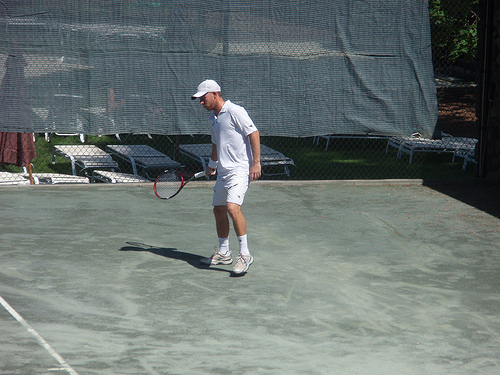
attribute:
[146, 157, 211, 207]
racket —  red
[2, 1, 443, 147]
net — green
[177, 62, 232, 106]
hat — white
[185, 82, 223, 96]
hat — white 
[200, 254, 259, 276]
shoes — pair, white 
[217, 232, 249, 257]
socks — white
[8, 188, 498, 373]
court — Tennis 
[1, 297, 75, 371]
line — white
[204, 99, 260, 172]
shirt — white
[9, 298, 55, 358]
line — white 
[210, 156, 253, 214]
shorts — white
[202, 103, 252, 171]
t-shirt — white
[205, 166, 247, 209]
trouser — shorts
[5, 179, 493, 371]
tennis court — grey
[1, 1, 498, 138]
tarp — grey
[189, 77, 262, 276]
man —  behind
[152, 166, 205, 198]
racket — red, black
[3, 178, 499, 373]
turf — faded green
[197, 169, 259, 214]
shorts — white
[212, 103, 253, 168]
shirt — white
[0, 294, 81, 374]
line — white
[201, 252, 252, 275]
shoes —  tennis 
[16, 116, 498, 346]
tennis court — tennis 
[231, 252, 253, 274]
shoe — tan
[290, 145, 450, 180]
grass — green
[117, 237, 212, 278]
shadow — man's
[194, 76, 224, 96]
hat — white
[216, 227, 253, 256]
socks — pair, white 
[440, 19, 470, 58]
branches — green